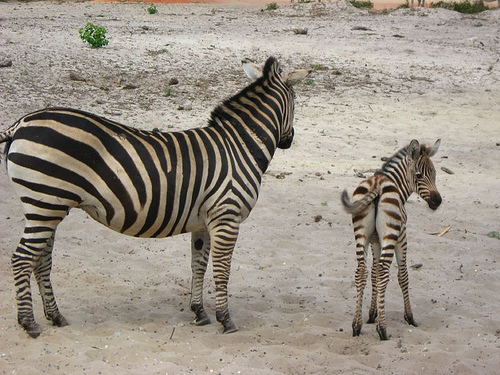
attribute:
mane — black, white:
[208, 66, 259, 120]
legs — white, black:
[3, 243, 285, 361]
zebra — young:
[323, 135, 462, 360]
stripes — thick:
[28, 112, 250, 237]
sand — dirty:
[0, 2, 497, 374]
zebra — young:
[340, 139, 455, 341]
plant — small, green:
[76, 17, 117, 49]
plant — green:
[77, 21, 105, 56]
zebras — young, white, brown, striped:
[339, 132, 438, 327]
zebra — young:
[332, 126, 464, 372]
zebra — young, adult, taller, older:
[0, 51, 308, 342]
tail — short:
[1, 126, 20, 142]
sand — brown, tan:
[294, 30, 498, 133]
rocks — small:
[60, 57, 205, 102]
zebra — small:
[328, 118, 453, 353]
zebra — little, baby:
[343, 142, 441, 339]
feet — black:
[181, 310, 236, 331]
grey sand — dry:
[1, 5, 498, 373]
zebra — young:
[329, 150, 461, 336]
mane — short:
[377, 136, 419, 171]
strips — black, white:
[104, 145, 174, 208]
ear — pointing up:
[430, 133, 442, 154]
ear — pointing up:
[408, 137, 419, 154]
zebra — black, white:
[326, 160, 458, 237]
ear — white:
[280, 54, 316, 86]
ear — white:
[242, 54, 260, 82]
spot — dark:
[192, 233, 205, 253]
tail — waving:
[325, 182, 392, 222]